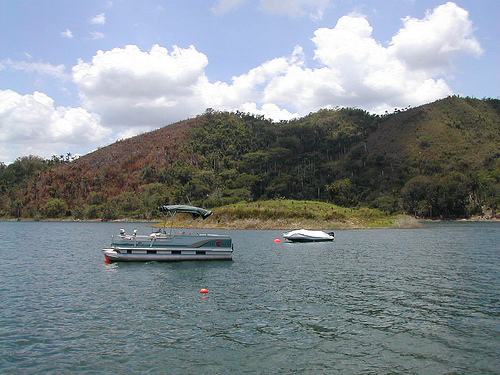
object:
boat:
[101, 204, 232, 261]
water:
[0, 218, 499, 373]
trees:
[35, 197, 69, 221]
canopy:
[156, 205, 212, 218]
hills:
[330, 95, 500, 221]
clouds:
[0, 87, 114, 166]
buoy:
[198, 287, 210, 293]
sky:
[0, 0, 499, 165]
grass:
[148, 197, 411, 228]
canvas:
[159, 204, 211, 219]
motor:
[327, 230, 335, 239]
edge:
[73, 265, 108, 285]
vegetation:
[0, 153, 68, 194]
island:
[155, 198, 420, 230]